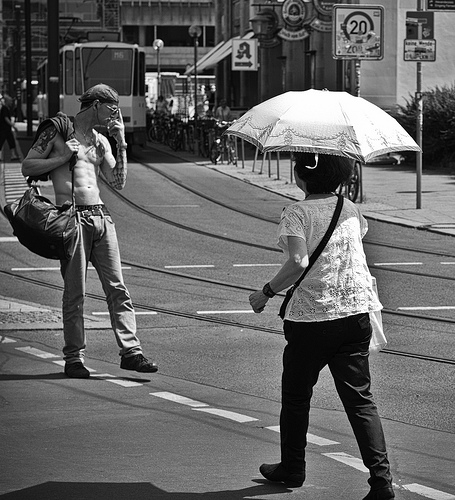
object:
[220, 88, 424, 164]
umbrella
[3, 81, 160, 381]
people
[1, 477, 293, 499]
shadow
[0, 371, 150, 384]
shadow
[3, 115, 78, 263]
bag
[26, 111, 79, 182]
shirt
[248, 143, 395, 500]
people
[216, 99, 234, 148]
people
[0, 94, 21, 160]
people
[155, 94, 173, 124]
people